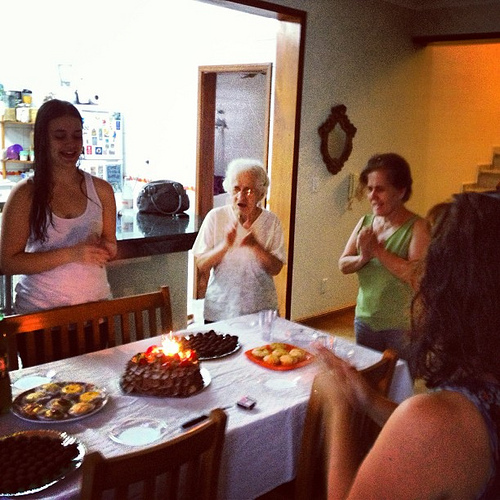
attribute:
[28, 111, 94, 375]
girl — standing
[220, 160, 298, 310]
lady — standing, older, clapping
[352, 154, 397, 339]
woman — standing, happy, older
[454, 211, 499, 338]
hair — brown, curly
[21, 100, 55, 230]
hair — long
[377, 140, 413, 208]
hair — short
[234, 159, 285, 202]
hair — white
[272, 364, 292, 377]
plate — orange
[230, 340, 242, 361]
plate — silver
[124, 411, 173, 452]
plate — plastic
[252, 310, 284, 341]
cups — clear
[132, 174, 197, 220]
purse — grey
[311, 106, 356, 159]
mirror — brown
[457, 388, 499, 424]
top — blue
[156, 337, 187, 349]
candle — lit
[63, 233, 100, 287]
top — white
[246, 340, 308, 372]
dish — orange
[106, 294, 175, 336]
chair — wood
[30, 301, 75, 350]
chair — wood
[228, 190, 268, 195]
glasses — wire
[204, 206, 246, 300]
blouse — white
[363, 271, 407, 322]
top — green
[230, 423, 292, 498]
tablecloth — white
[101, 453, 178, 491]
chair — wood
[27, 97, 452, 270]
people — celebrating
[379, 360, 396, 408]
chair — wood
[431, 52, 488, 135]
light — on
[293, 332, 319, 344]
plate — white